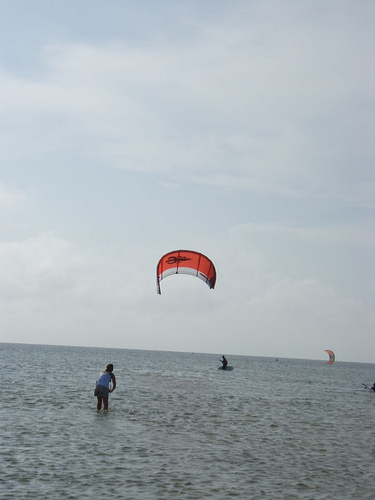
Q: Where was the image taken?
A: It was taken at the lake.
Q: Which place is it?
A: It is a lake.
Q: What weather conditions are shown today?
A: It is cloudy.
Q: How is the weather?
A: It is cloudy.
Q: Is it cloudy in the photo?
A: Yes, it is cloudy.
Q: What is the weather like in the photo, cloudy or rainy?
A: It is cloudy.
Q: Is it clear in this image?
A: No, it is cloudy.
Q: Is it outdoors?
A: Yes, it is outdoors.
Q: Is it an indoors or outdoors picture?
A: It is outdoors.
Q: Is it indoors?
A: No, it is outdoors.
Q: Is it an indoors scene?
A: No, it is outdoors.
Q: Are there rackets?
A: No, there are no rackets.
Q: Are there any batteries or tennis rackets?
A: No, there are no tennis rackets or batteries.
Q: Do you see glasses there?
A: No, there are no glasses.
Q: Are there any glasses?
A: No, there are no glasses.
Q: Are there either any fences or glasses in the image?
A: No, there are no glasses or fences.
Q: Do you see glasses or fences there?
A: No, there are no glasses or fences.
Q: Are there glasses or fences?
A: No, there are no glasses or fences.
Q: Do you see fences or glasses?
A: No, there are no glasses or fences.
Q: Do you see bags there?
A: No, there are no bags.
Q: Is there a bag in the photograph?
A: No, there are no bags.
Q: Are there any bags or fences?
A: No, there are no bags or fences.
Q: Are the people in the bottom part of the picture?
A: Yes, the people are in the bottom of the image.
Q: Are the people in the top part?
A: No, the people are in the bottom of the image.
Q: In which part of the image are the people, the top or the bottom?
A: The people are in the bottom of the image.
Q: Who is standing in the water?
A: The people are standing in the water.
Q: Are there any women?
A: Yes, there is a woman.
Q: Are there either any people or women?
A: Yes, there is a woman.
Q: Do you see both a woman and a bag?
A: No, there is a woman but no bags.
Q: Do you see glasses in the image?
A: No, there are no glasses.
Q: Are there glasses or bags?
A: No, there are no glasses or bags.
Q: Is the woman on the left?
A: Yes, the woman is on the left of the image.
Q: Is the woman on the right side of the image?
A: No, the woman is on the left of the image.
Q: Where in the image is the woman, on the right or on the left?
A: The woman is on the left of the image.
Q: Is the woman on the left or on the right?
A: The woman is on the left of the image.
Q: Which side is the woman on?
A: The woman is on the left of the image.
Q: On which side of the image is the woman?
A: The woman is on the left of the image.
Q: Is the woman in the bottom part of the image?
A: Yes, the woman is in the bottom of the image.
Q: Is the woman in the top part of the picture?
A: No, the woman is in the bottom of the image.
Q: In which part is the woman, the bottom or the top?
A: The woman is in the bottom of the image.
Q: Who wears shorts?
A: The woman wears shorts.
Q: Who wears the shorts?
A: The woman wears shorts.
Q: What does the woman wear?
A: The woman wears shorts.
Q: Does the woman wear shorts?
A: Yes, the woman wears shorts.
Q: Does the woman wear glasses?
A: No, the woman wears shorts.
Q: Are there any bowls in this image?
A: No, there are no bowls.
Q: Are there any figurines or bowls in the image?
A: No, there are no bowls or figurines.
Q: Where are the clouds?
A: The clouds are in the sky.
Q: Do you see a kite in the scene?
A: Yes, there is a kite.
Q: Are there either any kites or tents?
A: Yes, there is a kite.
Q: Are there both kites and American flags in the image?
A: No, there is a kite but no American flags.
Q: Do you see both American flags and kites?
A: No, there is a kite but no American flags.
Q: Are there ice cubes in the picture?
A: No, there are no ice cubes.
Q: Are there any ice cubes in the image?
A: No, there are no ice cubes.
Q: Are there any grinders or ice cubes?
A: No, there are no ice cubes or grinders.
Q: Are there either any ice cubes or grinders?
A: No, there are no ice cubes or grinders.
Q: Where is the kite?
A: The kite is in the sky.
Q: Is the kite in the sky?
A: Yes, the kite is in the sky.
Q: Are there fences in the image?
A: No, there are no fences.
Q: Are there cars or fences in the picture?
A: No, there are no fences or cars.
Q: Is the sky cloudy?
A: Yes, the sky is cloudy.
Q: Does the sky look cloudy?
A: Yes, the sky is cloudy.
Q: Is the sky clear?
A: No, the sky is cloudy.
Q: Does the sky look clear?
A: No, the sky is cloudy.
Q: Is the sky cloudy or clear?
A: The sky is cloudy.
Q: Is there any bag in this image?
A: No, there are no bags.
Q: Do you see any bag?
A: No, there are no bags.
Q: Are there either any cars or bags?
A: No, there are no bags or cars.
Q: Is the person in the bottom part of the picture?
A: Yes, the person is in the bottom of the image.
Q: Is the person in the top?
A: No, the person is in the bottom of the image.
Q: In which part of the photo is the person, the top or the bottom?
A: The person is in the bottom of the image.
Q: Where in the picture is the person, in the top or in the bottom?
A: The person is in the bottom of the image.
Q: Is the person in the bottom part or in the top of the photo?
A: The person is in the bottom of the image.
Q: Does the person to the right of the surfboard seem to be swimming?
A: Yes, the person is swimming.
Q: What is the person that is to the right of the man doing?
A: The person is swimming.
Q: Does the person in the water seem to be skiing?
A: No, the person is swimming.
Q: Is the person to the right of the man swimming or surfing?
A: The person is swimming.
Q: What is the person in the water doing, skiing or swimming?
A: The person is swimming.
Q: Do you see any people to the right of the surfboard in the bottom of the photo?
A: Yes, there is a person to the right of the surfboard.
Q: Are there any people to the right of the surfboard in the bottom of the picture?
A: Yes, there is a person to the right of the surfboard.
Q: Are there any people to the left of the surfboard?
A: No, the person is to the right of the surfboard.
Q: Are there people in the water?
A: Yes, there is a person in the water.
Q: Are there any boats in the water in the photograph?
A: No, there is a person in the water.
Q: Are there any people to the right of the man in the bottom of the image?
A: Yes, there is a person to the right of the man.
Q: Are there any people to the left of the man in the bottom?
A: No, the person is to the right of the man.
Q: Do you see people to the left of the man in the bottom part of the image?
A: No, the person is to the right of the man.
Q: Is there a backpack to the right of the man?
A: No, there is a person to the right of the man.